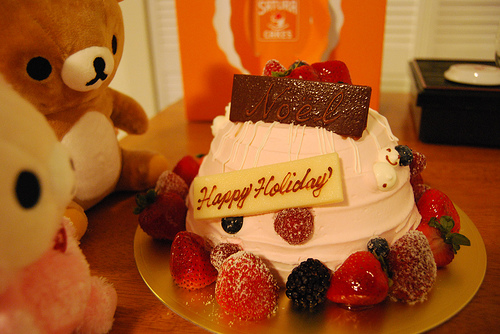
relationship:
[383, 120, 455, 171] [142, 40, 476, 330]
ground on cake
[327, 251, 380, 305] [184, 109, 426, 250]
berries around cake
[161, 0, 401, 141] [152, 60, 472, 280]
sign behind cake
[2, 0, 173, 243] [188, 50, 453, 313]
bear around cake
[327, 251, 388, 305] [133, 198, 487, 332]
berries on platter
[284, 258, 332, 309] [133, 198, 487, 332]
berries on platter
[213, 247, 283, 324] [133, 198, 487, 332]
berry on platter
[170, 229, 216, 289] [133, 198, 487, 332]
berry on platter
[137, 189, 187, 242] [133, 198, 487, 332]
berry on platter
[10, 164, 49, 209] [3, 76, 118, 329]
toy eye on animal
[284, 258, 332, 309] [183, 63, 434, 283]
berries on bottom of cake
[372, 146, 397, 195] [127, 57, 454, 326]
icing on holiday cake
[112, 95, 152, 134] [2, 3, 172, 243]
paw on bear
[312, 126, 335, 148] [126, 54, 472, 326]
drizzles are on cake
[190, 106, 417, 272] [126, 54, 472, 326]
icing on cake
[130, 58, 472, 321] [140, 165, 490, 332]
cake on teddy platter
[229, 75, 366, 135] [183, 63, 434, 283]
chocolate on top of cake